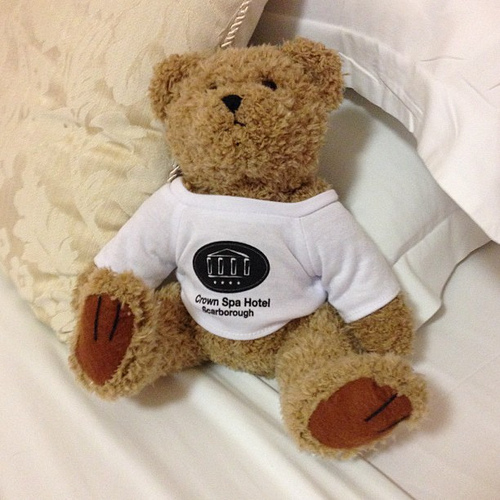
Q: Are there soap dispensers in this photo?
A: No, there are no soap dispensers.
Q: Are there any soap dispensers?
A: No, there are no soap dispensers.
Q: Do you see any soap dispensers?
A: No, there are no soap dispensers.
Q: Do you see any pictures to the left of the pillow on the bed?
A: Yes, there is a picture to the left of the pillow.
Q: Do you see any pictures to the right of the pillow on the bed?
A: No, the picture is to the left of the pillow.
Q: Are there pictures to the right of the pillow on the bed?
A: No, the picture is to the left of the pillow.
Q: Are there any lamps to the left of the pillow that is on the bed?
A: No, there is a picture to the left of the pillow.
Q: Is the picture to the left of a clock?
A: No, the picture is to the left of the pillow.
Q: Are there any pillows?
A: Yes, there is a pillow.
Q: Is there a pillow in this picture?
A: Yes, there is a pillow.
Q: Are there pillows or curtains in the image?
A: Yes, there is a pillow.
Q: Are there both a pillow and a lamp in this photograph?
A: No, there is a pillow but no lamps.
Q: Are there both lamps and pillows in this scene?
A: No, there is a pillow but no lamps.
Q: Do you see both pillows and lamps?
A: No, there is a pillow but no lamps.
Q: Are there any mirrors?
A: No, there are no mirrors.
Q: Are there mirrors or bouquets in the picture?
A: No, there are no mirrors or bouquets.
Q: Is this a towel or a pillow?
A: This is a pillow.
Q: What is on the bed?
A: The pillow is on the bed.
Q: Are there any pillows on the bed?
A: Yes, there is a pillow on the bed.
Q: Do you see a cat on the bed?
A: No, there is a pillow on the bed.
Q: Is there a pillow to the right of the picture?
A: Yes, there is a pillow to the right of the picture.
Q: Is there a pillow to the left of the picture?
A: No, the pillow is to the right of the picture.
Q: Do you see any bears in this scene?
A: Yes, there is a bear.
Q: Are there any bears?
A: Yes, there is a bear.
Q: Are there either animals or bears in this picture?
A: Yes, there is a bear.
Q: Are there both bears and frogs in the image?
A: No, there is a bear but no frogs.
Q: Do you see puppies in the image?
A: No, there are no puppies.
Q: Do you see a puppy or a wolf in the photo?
A: No, there are no puppies or wolves.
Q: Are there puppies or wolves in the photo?
A: No, there are no puppies or wolves.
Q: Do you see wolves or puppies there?
A: No, there are no puppies or wolves.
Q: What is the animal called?
A: The animal is a bear.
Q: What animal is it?
A: The animal is a bear.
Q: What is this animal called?
A: That is a bear.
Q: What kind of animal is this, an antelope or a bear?
A: That is a bear.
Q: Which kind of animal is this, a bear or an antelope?
A: That is a bear.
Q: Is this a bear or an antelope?
A: This is a bear.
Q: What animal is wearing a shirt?
A: The bear is wearing a shirt.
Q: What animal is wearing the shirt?
A: The bear is wearing a shirt.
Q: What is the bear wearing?
A: The bear is wearing a shirt.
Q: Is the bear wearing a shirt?
A: Yes, the bear is wearing a shirt.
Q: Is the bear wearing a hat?
A: No, the bear is wearing a shirt.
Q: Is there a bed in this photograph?
A: Yes, there is a bed.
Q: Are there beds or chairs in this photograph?
A: Yes, there is a bed.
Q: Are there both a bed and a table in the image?
A: No, there is a bed but no tables.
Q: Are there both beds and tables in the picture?
A: No, there is a bed but no tables.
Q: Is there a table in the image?
A: No, there are no tables.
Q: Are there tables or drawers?
A: No, there are no tables or drawers.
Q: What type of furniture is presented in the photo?
A: The furniture is a bed.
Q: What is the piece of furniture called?
A: The piece of furniture is a bed.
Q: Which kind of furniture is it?
A: The piece of furniture is a bed.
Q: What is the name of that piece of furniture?
A: This is a bed.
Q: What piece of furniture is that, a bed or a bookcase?
A: This is a bed.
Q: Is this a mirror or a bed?
A: This is a bed.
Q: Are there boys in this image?
A: No, there are no boys.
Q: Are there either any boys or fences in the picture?
A: No, there are no boys or fences.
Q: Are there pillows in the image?
A: Yes, there is a pillow.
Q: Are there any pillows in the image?
A: Yes, there is a pillow.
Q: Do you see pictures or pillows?
A: Yes, there is a pillow.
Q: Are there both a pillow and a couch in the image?
A: No, there is a pillow but no couches.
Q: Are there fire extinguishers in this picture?
A: No, there are no fire extinguishers.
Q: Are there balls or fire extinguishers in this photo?
A: No, there are no fire extinguishers or balls.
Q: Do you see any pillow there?
A: Yes, there is a pillow.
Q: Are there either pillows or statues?
A: Yes, there is a pillow.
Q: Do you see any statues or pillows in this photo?
A: Yes, there is a pillow.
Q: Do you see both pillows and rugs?
A: No, there is a pillow but no rugs.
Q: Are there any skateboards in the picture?
A: No, there are no skateboards.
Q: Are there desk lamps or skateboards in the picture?
A: No, there are no skateboards or desk lamps.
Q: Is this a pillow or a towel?
A: This is a pillow.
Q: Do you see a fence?
A: No, there are no fences.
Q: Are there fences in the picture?
A: No, there are no fences.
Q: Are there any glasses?
A: No, there are no glasses.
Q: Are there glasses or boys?
A: No, there are no glasses or boys.